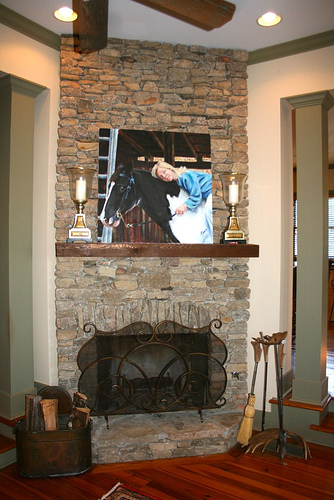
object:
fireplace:
[55, 34, 262, 465]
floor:
[1, 446, 334, 499]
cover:
[75, 318, 229, 420]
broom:
[235, 337, 261, 447]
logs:
[40, 394, 60, 431]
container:
[14, 409, 96, 478]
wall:
[247, 32, 333, 447]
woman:
[151, 159, 216, 241]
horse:
[100, 165, 213, 242]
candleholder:
[217, 171, 249, 245]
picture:
[96, 126, 212, 245]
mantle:
[53, 242, 259, 262]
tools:
[267, 328, 290, 460]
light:
[256, 11, 280, 29]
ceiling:
[3, 1, 332, 55]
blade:
[136, 1, 235, 31]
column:
[286, 92, 334, 405]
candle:
[228, 182, 238, 203]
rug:
[98, 481, 157, 500]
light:
[52, 5, 76, 22]